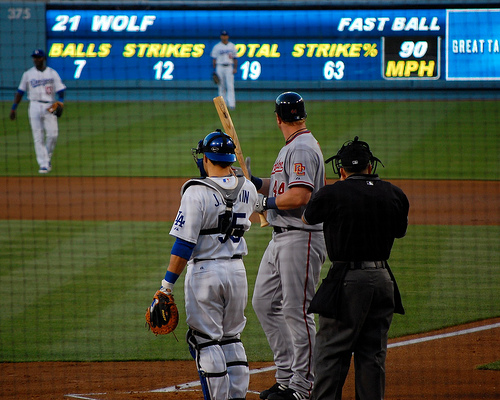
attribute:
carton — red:
[136, 278, 199, 341]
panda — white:
[5, 59, 93, 155]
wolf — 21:
[55, 4, 163, 45]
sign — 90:
[377, 17, 459, 101]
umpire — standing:
[287, 92, 461, 391]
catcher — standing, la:
[10, 36, 96, 190]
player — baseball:
[20, 41, 109, 179]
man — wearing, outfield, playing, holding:
[213, 26, 235, 51]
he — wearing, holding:
[110, 123, 307, 387]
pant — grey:
[321, 290, 410, 366]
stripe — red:
[271, 231, 339, 391]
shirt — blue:
[155, 232, 198, 271]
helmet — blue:
[196, 138, 242, 166]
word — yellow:
[122, 25, 210, 61]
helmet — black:
[260, 85, 322, 127]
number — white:
[392, 37, 435, 66]